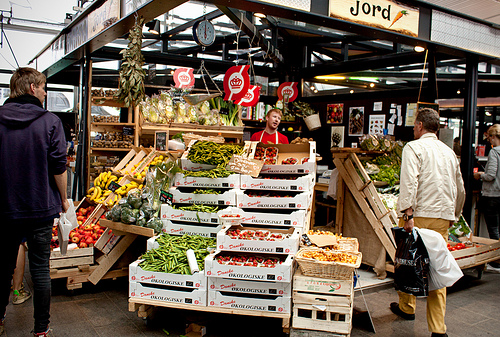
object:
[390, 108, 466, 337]
man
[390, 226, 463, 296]
bag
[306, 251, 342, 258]
vegetable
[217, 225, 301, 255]
case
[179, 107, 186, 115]
orange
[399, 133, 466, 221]
jacket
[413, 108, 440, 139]
head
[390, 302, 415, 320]
shoe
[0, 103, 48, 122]
hoody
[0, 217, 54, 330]
jean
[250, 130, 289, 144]
shirt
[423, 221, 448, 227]
pant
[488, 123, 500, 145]
head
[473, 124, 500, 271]
woman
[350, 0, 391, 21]
word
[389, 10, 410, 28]
carrot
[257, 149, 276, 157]
fruit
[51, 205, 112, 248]
apple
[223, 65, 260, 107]
sign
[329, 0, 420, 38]
picture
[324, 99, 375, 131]
wall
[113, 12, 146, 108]
good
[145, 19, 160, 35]
light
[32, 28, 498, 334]
shop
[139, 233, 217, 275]
bean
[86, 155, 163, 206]
banana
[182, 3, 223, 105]
machine